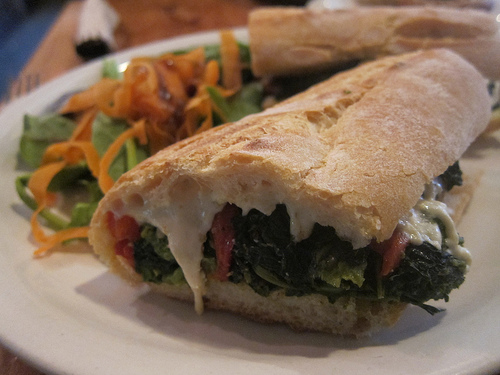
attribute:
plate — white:
[6, 24, 496, 373]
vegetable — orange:
[62, 25, 238, 141]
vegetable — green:
[377, 238, 470, 307]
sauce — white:
[119, 178, 447, 307]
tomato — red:
[209, 203, 242, 283]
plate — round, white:
[2, 16, 425, 370]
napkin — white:
[75, 8, 129, 54]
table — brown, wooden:
[18, 6, 259, 103]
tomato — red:
[194, 199, 258, 287]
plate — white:
[32, 60, 467, 366]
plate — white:
[7, 43, 434, 370]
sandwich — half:
[80, 38, 483, 340]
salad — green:
[32, 30, 309, 215]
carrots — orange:
[97, 57, 250, 199]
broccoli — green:
[226, 216, 422, 300]